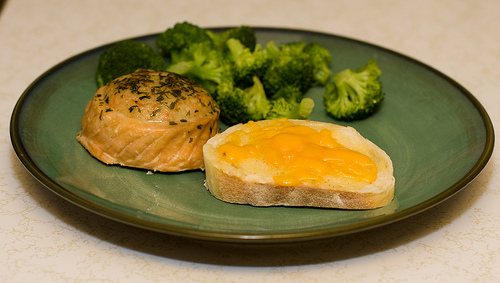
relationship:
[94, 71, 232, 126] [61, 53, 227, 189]
specks on food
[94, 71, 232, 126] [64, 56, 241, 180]
specks on food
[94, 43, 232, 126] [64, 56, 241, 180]
specks on food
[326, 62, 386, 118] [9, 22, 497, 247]
broccoli on plate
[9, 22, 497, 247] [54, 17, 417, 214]
plate of food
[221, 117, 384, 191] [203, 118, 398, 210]
cheese on bread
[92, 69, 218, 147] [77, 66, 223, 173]
herbs sprinkled on fish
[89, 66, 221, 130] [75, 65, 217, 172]
seasoning on meat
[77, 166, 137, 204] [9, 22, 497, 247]
shadow on plate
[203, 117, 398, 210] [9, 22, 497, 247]
bread on plate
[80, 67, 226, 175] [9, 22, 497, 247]
food on plate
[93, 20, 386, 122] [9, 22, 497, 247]
broccoli on plate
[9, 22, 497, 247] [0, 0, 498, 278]
plate on counter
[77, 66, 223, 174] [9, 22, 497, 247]
fish on plate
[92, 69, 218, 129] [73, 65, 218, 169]
herbs on fish